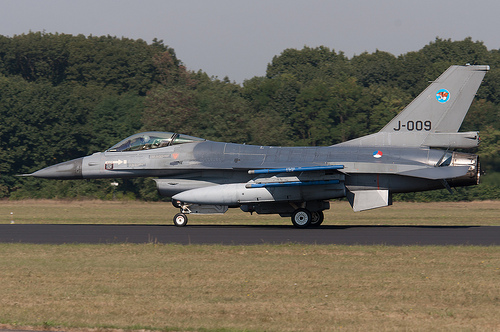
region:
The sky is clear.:
[165, 16, 256, 64]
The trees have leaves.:
[10, 38, 181, 123]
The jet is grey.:
[36, 66, 487, 236]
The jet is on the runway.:
[36, 88, 493, 249]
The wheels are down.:
[33, 75, 485, 255]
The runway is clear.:
[27, 198, 498, 259]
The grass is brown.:
[19, 246, 480, 317]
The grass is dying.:
[17, 255, 487, 317]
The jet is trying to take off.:
[13, 71, 490, 233]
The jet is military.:
[12, 46, 489, 266]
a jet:
[12, 23, 490, 271]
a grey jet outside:
[23, 37, 494, 301]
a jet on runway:
[49, 47, 495, 269]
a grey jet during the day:
[22, 39, 498, 317]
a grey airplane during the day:
[12, 31, 497, 278]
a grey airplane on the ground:
[29, 28, 499, 278]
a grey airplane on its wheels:
[15, 31, 460, 328]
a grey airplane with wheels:
[14, 16, 496, 230]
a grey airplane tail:
[319, 29, 494, 220]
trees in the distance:
[18, 7, 342, 172]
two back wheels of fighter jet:
[278, 207, 351, 239]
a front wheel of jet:
[166, 208, 205, 235]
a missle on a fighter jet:
[176, 183, 338, 204]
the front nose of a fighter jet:
[0, 125, 88, 192]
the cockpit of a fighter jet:
[108, 127, 202, 153]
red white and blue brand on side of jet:
[368, 145, 400, 160]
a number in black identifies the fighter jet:
[357, 112, 453, 137]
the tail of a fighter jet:
[343, 74, 498, 141]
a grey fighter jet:
[9, 55, 499, 236]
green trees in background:
[13, 37, 497, 228]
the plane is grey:
[34, 55, 408, 255]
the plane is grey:
[65, 100, 337, 235]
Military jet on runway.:
[17, 42, 497, 299]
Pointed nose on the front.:
[6, 151, 97, 180]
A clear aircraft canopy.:
[103, 116, 208, 157]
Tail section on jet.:
[380, 46, 487, 153]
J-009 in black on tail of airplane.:
[388, 114, 442, 137]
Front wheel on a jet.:
[165, 200, 199, 232]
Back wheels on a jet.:
[284, 205, 334, 235]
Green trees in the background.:
[2, 23, 494, 204]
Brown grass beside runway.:
[12, 235, 452, 330]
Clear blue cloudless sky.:
[5, 4, 487, 41]